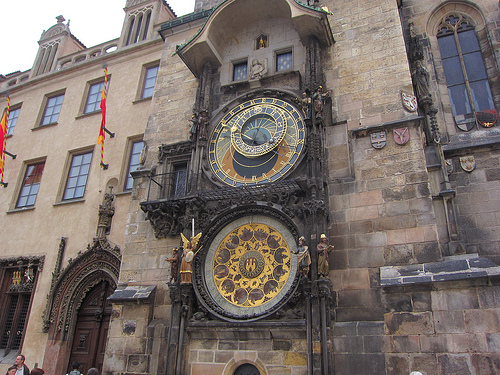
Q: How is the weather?
A: It is cloudless.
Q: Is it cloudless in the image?
A: Yes, it is cloudless.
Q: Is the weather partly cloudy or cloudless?
A: It is cloudless.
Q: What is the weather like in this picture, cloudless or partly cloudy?
A: It is cloudless.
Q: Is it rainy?
A: No, it is cloudless.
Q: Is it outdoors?
A: Yes, it is outdoors.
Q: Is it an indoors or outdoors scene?
A: It is outdoors.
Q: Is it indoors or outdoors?
A: It is outdoors.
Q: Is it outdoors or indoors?
A: It is outdoors.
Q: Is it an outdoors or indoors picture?
A: It is outdoors.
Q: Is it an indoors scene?
A: No, it is outdoors.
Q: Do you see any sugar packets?
A: No, there are no sugar packets.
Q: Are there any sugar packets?
A: No, there are no sugar packets.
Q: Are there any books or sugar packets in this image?
A: No, there are no sugar packets or books.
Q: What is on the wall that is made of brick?
A: The shield is on the wall.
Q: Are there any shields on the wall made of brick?
A: Yes, there is a shield on the wall.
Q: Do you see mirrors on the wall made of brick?
A: No, there is a shield on the wall.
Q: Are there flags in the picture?
A: Yes, there is a flag.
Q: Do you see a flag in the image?
A: Yes, there is a flag.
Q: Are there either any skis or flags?
A: Yes, there is a flag.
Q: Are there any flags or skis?
A: Yes, there is a flag.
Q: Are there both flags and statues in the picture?
A: Yes, there are both a flag and a statue.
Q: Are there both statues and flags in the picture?
A: Yes, there are both a flag and a statue.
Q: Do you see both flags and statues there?
A: Yes, there are both a flag and a statue.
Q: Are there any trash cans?
A: No, there are no trash cans.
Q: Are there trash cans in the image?
A: No, there are no trash cans.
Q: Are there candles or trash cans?
A: No, there are no trash cans or candles.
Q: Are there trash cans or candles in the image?
A: No, there are no trash cans or candles.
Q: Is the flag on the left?
A: Yes, the flag is on the left of the image.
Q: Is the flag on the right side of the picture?
A: No, the flag is on the left of the image.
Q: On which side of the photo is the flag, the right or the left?
A: The flag is on the left of the image.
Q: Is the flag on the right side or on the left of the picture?
A: The flag is on the left of the image.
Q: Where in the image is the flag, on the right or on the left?
A: The flag is on the left of the image.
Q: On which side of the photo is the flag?
A: The flag is on the left of the image.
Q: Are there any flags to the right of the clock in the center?
A: No, the flag is to the left of the clock.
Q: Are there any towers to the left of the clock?
A: No, there is a flag to the left of the clock.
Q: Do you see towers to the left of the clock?
A: No, there is a flag to the left of the clock.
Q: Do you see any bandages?
A: No, there are no bandages.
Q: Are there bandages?
A: No, there are no bandages.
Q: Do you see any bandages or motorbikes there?
A: No, there are no bandages or motorbikes.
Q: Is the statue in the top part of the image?
A: Yes, the statue is in the top of the image.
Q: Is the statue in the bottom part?
A: No, the statue is in the top of the image.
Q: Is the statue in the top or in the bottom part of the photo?
A: The statue is in the top of the image.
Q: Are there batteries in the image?
A: No, there are no batteries.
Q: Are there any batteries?
A: No, there are no batteries.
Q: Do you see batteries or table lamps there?
A: No, there are no batteries or table lamps.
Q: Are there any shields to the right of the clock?
A: Yes, there is a shield to the right of the clock.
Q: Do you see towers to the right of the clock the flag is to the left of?
A: No, there is a shield to the right of the clock.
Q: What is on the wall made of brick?
A: The shield is on the wall.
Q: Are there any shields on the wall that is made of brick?
A: Yes, there is a shield on the wall.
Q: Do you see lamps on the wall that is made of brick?
A: No, there is a shield on the wall.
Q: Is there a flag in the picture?
A: Yes, there is a flag.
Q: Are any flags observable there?
A: Yes, there is a flag.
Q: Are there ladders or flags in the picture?
A: Yes, there is a flag.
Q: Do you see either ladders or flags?
A: Yes, there is a flag.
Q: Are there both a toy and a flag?
A: No, there is a flag but no toys.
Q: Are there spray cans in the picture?
A: No, there are no spray cans.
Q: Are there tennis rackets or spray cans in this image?
A: No, there are no spray cans or tennis rackets.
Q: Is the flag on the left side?
A: Yes, the flag is on the left of the image.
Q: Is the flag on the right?
A: No, the flag is on the left of the image.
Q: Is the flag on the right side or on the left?
A: The flag is on the left of the image.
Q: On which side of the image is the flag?
A: The flag is on the left of the image.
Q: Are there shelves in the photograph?
A: No, there are no shelves.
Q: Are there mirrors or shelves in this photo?
A: No, there are no shelves or mirrors.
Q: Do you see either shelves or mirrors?
A: No, there are no shelves or mirrors.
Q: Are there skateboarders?
A: No, there are no skateboarders.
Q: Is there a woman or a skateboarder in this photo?
A: No, there are no skateboarders or women.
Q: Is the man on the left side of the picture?
A: Yes, the man is on the left of the image.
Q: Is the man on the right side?
A: No, the man is on the left of the image.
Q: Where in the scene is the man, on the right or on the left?
A: The man is on the left of the image.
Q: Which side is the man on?
A: The man is on the left of the image.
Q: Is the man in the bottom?
A: Yes, the man is in the bottom of the image.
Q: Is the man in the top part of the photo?
A: No, the man is in the bottom of the image.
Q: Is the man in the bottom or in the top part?
A: The man is in the bottom of the image.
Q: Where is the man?
A: The man is on the street.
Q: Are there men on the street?
A: Yes, there is a man on the street.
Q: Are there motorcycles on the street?
A: No, there is a man on the street.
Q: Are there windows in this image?
A: Yes, there is a window.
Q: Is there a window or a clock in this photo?
A: Yes, there is a window.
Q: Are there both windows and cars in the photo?
A: No, there is a window but no cars.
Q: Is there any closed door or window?
A: Yes, there is a closed window.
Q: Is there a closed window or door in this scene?
A: Yes, there is a closed window.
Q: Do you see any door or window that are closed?
A: Yes, the window is closed.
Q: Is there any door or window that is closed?
A: Yes, the window is closed.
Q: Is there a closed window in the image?
A: Yes, there is a closed window.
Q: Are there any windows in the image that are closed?
A: Yes, there is a window that is closed.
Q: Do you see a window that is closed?
A: Yes, there is a window that is closed.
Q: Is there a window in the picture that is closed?
A: Yes, there is a window that is closed.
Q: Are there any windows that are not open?
A: Yes, there is an closed window.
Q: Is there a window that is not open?
A: Yes, there is an closed window.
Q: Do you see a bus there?
A: No, there are no buses.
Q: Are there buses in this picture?
A: No, there are no buses.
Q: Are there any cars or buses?
A: No, there are no buses or cars.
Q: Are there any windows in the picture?
A: Yes, there is a window.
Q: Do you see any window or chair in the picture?
A: Yes, there is a window.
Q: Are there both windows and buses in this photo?
A: No, there is a window but no buses.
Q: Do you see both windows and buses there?
A: No, there is a window but no buses.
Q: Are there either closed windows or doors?
A: Yes, there is a closed window.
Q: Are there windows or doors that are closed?
A: Yes, the window is closed.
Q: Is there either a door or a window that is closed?
A: Yes, the window is closed.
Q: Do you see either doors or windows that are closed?
A: Yes, the window is closed.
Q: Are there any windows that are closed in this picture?
A: Yes, there is a closed window.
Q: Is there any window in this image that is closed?
A: Yes, there is a window that is closed.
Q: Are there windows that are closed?
A: Yes, there is a window that is closed.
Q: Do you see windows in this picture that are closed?
A: Yes, there is a window that is closed.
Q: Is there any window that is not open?
A: Yes, there is an closed window.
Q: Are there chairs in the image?
A: No, there are no chairs.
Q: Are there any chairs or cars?
A: No, there are no chairs or cars.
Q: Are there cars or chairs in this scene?
A: No, there are no chairs or cars.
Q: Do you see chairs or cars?
A: No, there are no chairs or cars.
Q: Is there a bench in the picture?
A: No, there are no benches.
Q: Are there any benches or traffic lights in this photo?
A: No, there are no benches or traffic lights.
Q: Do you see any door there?
A: Yes, there is a door.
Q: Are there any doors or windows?
A: Yes, there is a door.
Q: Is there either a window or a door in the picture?
A: Yes, there is a door.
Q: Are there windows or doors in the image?
A: Yes, there is a door.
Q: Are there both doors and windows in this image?
A: Yes, there are both a door and windows.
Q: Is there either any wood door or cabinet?
A: Yes, there is a wood door.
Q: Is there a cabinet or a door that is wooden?
A: Yes, the door is wooden.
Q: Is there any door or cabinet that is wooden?
A: Yes, the door is wooden.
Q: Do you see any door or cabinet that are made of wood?
A: Yes, the door is made of wood.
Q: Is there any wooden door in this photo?
A: Yes, there is a wood door.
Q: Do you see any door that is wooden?
A: Yes, there is a wood door.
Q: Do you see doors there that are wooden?
A: Yes, there is a wood door.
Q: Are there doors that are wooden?
A: Yes, there is a door that is wooden.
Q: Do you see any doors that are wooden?
A: Yes, there is a door that is wooden.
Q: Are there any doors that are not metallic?
A: Yes, there is a wooden door.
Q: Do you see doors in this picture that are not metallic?
A: Yes, there is a wooden door.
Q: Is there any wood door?
A: Yes, there is a door that is made of wood.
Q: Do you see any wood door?
A: Yes, there is a door that is made of wood.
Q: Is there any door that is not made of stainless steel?
A: Yes, there is a door that is made of wood.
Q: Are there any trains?
A: No, there are no trains.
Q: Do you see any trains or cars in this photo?
A: No, there are no trains or cars.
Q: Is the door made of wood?
A: Yes, the door is made of wood.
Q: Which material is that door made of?
A: The door is made of wood.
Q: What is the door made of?
A: The door is made of wood.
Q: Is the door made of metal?
A: No, the door is made of wood.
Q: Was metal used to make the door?
A: No, the door is made of wood.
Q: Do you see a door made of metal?
A: No, there is a door but it is made of wood.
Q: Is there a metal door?
A: No, there is a door but it is made of wood.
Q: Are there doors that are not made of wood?
A: No, there is a door but it is made of wood.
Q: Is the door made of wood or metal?
A: The door is made of wood.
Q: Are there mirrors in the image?
A: No, there are no mirrors.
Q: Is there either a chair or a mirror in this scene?
A: No, there are no mirrors or chairs.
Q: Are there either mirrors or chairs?
A: No, there are no mirrors or chairs.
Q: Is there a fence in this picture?
A: No, there are no fences.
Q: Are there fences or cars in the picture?
A: No, there are no fences or cars.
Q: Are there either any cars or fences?
A: No, there are no fences or cars.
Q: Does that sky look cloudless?
A: Yes, the sky is cloudless.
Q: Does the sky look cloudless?
A: Yes, the sky is cloudless.